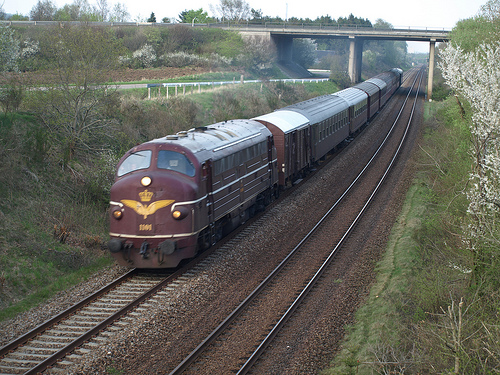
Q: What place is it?
A: It is a railroad.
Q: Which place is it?
A: It is a railroad.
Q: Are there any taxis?
A: No, there are no taxis.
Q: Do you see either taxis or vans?
A: No, there are no taxis or vans.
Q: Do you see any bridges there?
A: Yes, there is a bridge.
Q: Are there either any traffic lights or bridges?
A: Yes, there is a bridge.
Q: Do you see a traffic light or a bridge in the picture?
A: Yes, there is a bridge.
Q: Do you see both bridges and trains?
A: Yes, there are both a bridge and a train.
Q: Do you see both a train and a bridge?
A: Yes, there are both a bridge and a train.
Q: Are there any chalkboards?
A: No, there are no chalkboards.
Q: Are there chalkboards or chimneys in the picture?
A: No, there are no chalkboards or chimneys.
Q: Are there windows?
A: Yes, there is a window.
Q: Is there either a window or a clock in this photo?
A: Yes, there is a window.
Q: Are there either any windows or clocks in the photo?
A: Yes, there is a window.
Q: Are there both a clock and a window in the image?
A: No, there is a window but no clocks.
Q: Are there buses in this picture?
A: No, there are no buses.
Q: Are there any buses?
A: No, there are no buses.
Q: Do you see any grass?
A: Yes, there is grass.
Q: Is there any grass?
A: Yes, there is grass.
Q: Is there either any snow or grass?
A: Yes, there is grass.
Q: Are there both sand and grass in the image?
A: No, there is grass but no sand.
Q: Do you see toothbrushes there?
A: No, there are no toothbrushes.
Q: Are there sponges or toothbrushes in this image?
A: No, there are no toothbrushes or sponges.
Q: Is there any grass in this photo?
A: Yes, there is grass.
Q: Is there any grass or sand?
A: Yes, there is grass.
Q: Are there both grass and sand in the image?
A: No, there is grass but no sand.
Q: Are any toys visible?
A: No, there are no toys.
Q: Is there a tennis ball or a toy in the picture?
A: No, there are no toys or tennis balls.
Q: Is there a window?
A: Yes, there is a window.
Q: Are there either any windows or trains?
A: Yes, there is a window.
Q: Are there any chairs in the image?
A: No, there are no chairs.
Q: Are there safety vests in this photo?
A: No, there are no safety vests.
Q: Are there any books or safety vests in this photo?
A: No, there are no safety vests or books.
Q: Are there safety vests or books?
A: No, there are no safety vests or books.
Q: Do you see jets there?
A: No, there are no jets.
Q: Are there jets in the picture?
A: No, there are no jets.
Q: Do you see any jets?
A: No, there are no jets.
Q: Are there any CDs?
A: No, there are no cds.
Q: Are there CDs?
A: No, there are no cds.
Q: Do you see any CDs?
A: No, there are no cds.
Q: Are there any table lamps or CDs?
A: No, there are no CDs or table lamps.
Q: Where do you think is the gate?
A: The gate is in the grass.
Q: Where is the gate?
A: The gate is in the grass.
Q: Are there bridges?
A: Yes, there is a bridge.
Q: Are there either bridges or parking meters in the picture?
A: Yes, there is a bridge.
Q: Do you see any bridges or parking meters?
A: Yes, there is a bridge.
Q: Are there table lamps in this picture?
A: No, there are no table lamps.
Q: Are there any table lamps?
A: No, there are no table lamps.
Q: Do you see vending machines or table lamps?
A: No, there are no table lamps or vending machines.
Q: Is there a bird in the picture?
A: Yes, there is a bird.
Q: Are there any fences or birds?
A: Yes, there is a bird.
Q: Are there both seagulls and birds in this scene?
A: No, there is a bird but no seagulls.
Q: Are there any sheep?
A: No, there are no sheep.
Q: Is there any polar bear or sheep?
A: No, there are no sheep or polar bears.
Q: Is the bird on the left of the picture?
A: Yes, the bird is on the left of the image.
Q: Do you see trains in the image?
A: Yes, there is a train.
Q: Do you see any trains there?
A: Yes, there is a train.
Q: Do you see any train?
A: Yes, there is a train.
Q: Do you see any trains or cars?
A: Yes, there is a train.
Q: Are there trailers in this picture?
A: No, there are no trailers.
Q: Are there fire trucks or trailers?
A: No, there are no trailers or fire trucks.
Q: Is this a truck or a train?
A: This is a train.